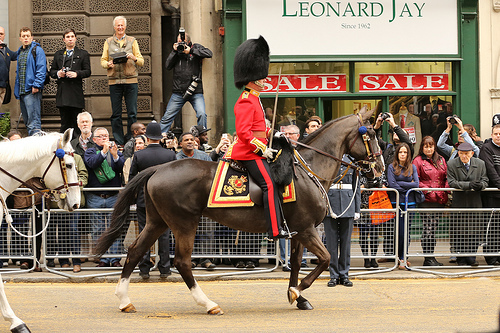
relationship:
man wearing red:
[233, 78, 286, 239] [239, 106, 251, 115]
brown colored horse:
[158, 185, 168, 200] [95, 107, 386, 316]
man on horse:
[233, 78, 286, 239] [95, 107, 386, 316]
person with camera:
[162, 28, 212, 149] [174, 28, 187, 54]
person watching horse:
[389, 143, 419, 269] [95, 107, 386, 316]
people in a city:
[112, 12, 398, 219] [5, 9, 496, 173]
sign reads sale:
[357, 73, 448, 93] [362, 75, 445, 89]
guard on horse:
[233, 35, 297, 238] [95, 107, 386, 316]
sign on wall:
[357, 73, 448, 93] [9, 2, 481, 105]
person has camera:
[436, 115, 480, 155] [448, 116, 460, 125]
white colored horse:
[11, 144, 34, 154] [1, 128, 81, 332]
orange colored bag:
[382, 201, 389, 210] [366, 191, 394, 225]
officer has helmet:
[233, 78, 286, 239] [235, 35, 270, 93]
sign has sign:
[357, 73, 448, 93] [357, 73, 448, 93]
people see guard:
[112, 12, 398, 219] [233, 35, 297, 238]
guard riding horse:
[233, 35, 297, 238] [95, 107, 386, 316]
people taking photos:
[99, 15, 146, 147] [113, 51, 128, 65]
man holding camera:
[51, 29, 90, 134] [60, 66, 77, 76]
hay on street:
[366, 275, 495, 294] [3, 281, 499, 329]